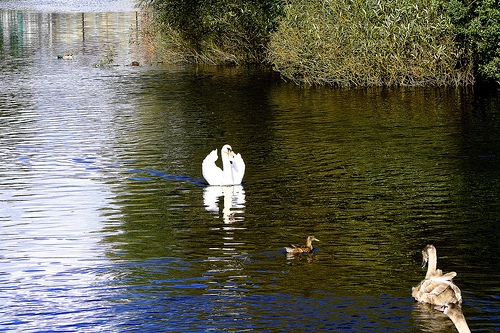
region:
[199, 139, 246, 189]
Swan in the river.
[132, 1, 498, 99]
Trees on the river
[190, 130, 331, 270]
Swan and duck in the river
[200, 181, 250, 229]
Swan's reflection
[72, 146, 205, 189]
Swan's swimming path in the river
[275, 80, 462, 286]
Tree's reflection in the river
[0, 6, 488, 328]
Large river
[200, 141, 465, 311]
Three birds on the water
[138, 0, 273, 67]
Dark green tree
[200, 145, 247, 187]
Two wings on the swan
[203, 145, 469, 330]
Birds are in the water.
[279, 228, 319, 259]
A duck is in the water.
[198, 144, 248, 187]
A white bird is flapping a wing.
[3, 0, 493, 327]
Water is moving and has ripples.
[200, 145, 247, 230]
A white bird is reflected in the water.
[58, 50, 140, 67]
Small ducks are near a splashing ripple.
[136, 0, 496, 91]
Green bushes are near water.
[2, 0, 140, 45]
Vertical lines are reflected in the water.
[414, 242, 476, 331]
A bird has a curved neck.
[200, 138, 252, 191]
a swan in the water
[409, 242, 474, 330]
a swan in the water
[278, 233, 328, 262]
a duck in the water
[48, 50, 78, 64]
an object in the water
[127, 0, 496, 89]
green shrubs above the water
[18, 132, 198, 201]
ripples in the water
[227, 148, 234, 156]
a swan's yellow beak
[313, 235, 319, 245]
a duck's yellow beak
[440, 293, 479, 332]
a brown swan's tail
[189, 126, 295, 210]
swan with outstretched wings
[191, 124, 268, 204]
swan in middle of water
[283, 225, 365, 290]
brown multicolored swimming duck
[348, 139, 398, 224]
multiple ripples on the water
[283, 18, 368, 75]
green colored brush in the distance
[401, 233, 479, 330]
brown colored swan facing away from photo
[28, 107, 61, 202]
bright colored portion of water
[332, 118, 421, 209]
shadowed color portion of water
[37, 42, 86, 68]
animal swimming in the distance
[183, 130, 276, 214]
swan swimming toward front of picture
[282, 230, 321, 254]
a little duck swimming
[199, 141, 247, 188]
a white swan swimming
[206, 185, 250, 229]
the reflection of the white swan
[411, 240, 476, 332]
a brown and white swan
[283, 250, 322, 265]
the reflection of the brown duck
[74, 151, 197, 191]
the ripples caused by the swan swimming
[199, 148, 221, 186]
right wing of the swan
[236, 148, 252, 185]
the swan's left wing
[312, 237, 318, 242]
beak of the brown duck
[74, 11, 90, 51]
reflection of a tree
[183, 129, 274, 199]
the swan is white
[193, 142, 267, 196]
a swan in the pond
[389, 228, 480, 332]
a brown duck in pond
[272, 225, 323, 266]
a small baby duck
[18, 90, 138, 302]
light reflecting on water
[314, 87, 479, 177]
the water is green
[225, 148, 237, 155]
the beck is yellow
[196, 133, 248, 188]
the feathers are ruffled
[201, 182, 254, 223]
the reflection of swan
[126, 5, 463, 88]
bushes by the pond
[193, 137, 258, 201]
white swan in water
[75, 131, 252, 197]
trail in water behind swan